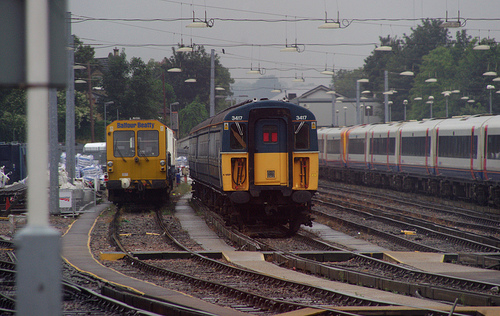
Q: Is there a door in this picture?
A: Yes, there is a door.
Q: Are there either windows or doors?
A: Yes, there is a door.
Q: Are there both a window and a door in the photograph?
A: Yes, there are both a door and a window.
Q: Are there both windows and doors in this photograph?
A: Yes, there are both a door and windows.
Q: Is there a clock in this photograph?
A: No, there are no clocks.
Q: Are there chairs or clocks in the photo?
A: No, there are no clocks or chairs.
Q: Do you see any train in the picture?
A: Yes, there are trains.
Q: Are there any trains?
A: Yes, there are trains.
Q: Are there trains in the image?
A: Yes, there are trains.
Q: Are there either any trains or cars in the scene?
A: Yes, there are trains.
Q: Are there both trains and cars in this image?
A: Yes, there are both trains and a car.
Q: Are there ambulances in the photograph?
A: No, there are no ambulances.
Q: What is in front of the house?
A: The trains are in front of the house.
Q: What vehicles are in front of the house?
A: The vehicles are trains.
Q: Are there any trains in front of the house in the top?
A: Yes, there are trains in front of the house.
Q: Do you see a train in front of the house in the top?
A: Yes, there are trains in front of the house.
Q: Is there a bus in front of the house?
A: No, there are trains in front of the house.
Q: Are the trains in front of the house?
A: Yes, the trains are in front of the house.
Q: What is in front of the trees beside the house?
A: The trains are in front of the trees.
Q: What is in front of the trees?
A: The trains are in front of the trees.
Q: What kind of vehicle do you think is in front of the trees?
A: The vehicles are trains.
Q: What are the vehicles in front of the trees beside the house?
A: The vehicles are trains.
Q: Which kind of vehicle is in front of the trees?
A: The vehicles are trains.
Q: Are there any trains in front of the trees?
A: Yes, there are trains in front of the trees.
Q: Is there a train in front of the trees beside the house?
A: Yes, there are trains in front of the trees.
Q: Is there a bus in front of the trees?
A: No, there are trains in front of the trees.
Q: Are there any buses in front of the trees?
A: No, there are trains in front of the trees.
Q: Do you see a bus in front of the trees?
A: No, there are trains in front of the trees.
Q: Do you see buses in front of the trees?
A: No, there are trains in front of the trees.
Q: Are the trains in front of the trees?
A: Yes, the trains are in front of the trees.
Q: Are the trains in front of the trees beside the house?
A: Yes, the trains are in front of the trees.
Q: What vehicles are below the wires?
A: The vehicles are trains.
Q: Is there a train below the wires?
A: Yes, there are trains below the wires.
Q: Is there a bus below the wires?
A: No, there are trains below the wires.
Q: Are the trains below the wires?
A: Yes, the trains are below the wires.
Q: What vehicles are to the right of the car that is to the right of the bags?
A: The vehicles are trains.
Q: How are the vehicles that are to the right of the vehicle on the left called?
A: The vehicles are trains.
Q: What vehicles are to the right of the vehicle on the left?
A: The vehicles are trains.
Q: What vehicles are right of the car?
A: The vehicles are trains.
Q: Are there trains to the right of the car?
A: Yes, there are trains to the right of the car.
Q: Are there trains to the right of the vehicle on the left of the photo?
A: Yes, there are trains to the right of the car.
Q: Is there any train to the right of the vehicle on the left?
A: Yes, there are trains to the right of the car.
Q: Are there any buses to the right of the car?
A: No, there are trains to the right of the car.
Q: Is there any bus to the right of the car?
A: No, there are trains to the right of the car.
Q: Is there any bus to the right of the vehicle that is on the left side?
A: No, there are trains to the right of the car.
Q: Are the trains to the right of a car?
A: Yes, the trains are to the right of a car.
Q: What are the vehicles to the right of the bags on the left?
A: The vehicles are trains.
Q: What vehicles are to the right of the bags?
A: The vehicles are trains.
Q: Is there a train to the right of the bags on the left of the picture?
A: Yes, there are trains to the right of the bags.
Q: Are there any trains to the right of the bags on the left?
A: Yes, there are trains to the right of the bags.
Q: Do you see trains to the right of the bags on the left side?
A: Yes, there are trains to the right of the bags.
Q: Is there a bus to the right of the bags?
A: No, there are trains to the right of the bags.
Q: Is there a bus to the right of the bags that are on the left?
A: No, there are trains to the right of the bags.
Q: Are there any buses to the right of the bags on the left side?
A: No, there are trains to the right of the bags.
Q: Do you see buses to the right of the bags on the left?
A: No, there are trains to the right of the bags.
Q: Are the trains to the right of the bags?
A: Yes, the trains are to the right of the bags.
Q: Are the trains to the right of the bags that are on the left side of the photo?
A: Yes, the trains are to the right of the bags.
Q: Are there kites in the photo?
A: No, there are no kites.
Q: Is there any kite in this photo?
A: No, there are no kites.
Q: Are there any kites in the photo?
A: No, there are no kites.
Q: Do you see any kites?
A: No, there are no kites.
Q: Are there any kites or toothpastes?
A: No, there are no kites or toothpastes.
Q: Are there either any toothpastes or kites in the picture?
A: No, there are no kites or toothpastes.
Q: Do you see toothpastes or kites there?
A: No, there are no kites or toothpastes.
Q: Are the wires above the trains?
A: Yes, the wires are above the trains.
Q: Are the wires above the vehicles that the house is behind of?
A: Yes, the wires are above the trains.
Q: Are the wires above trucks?
A: No, the wires are above the trains.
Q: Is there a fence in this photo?
A: No, there are no fences.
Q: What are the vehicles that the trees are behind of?
A: The vehicles are trains.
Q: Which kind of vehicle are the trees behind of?
A: The trees are behind the trains.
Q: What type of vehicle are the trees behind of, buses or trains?
A: The trees are behind trains.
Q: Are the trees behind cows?
A: No, the trees are behind the trains.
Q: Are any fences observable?
A: No, there are no fences.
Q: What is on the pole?
A: The sign is on the pole.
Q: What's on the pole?
A: The sign is on the pole.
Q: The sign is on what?
A: The sign is on the pole.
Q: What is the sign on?
A: The sign is on the pole.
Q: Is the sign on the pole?
A: Yes, the sign is on the pole.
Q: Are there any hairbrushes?
A: No, there are no hairbrushes.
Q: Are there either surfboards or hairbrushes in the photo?
A: No, there are no hairbrushes or surfboards.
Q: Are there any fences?
A: No, there are no fences.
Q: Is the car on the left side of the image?
A: Yes, the car is on the left of the image.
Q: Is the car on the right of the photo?
A: No, the car is on the left of the image.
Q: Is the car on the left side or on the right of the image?
A: The car is on the left of the image.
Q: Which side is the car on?
A: The car is on the left of the image.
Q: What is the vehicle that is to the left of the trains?
A: The vehicle is a car.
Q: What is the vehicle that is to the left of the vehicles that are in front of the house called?
A: The vehicle is a car.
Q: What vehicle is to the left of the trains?
A: The vehicle is a car.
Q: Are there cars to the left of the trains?
A: Yes, there is a car to the left of the trains.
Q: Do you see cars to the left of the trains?
A: Yes, there is a car to the left of the trains.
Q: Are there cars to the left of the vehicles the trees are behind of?
A: Yes, there is a car to the left of the trains.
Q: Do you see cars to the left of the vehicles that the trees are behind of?
A: Yes, there is a car to the left of the trains.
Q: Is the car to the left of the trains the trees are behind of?
A: Yes, the car is to the left of the trains.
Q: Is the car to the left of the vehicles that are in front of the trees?
A: Yes, the car is to the left of the trains.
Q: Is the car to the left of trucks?
A: No, the car is to the left of the trains.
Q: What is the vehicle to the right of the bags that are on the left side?
A: The vehicle is a car.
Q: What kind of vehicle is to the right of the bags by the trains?
A: The vehicle is a car.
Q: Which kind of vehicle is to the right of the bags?
A: The vehicle is a car.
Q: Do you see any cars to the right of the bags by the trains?
A: Yes, there is a car to the right of the bags.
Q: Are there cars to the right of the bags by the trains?
A: Yes, there is a car to the right of the bags.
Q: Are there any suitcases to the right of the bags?
A: No, there is a car to the right of the bags.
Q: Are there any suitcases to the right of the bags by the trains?
A: No, there is a car to the right of the bags.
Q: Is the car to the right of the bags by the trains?
A: Yes, the car is to the right of the bags.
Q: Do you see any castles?
A: No, there are no castles.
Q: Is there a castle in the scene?
A: No, there are no castles.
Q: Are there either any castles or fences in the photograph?
A: No, there are no castles or fences.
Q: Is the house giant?
A: Yes, the house is giant.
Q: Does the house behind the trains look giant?
A: Yes, the house is giant.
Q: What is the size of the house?
A: The house is giant.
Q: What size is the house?
A: The house is giant.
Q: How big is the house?
A: The house is giant.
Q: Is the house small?
A: No, the house is giant.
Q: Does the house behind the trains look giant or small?
A: The house is giant.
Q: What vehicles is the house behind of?
A: The house is behind the trains.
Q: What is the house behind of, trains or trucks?
A: The house is behind trains.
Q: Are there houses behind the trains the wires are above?
A: Yes, there is a house behind the trains.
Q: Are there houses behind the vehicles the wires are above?
A: Yes, there is a house behind the trains.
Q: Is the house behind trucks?
A: No, the house is behind the trains.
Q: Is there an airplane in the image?
A: No, there are no airplanes.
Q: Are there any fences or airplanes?
A: No, there are no airplanes or fences.